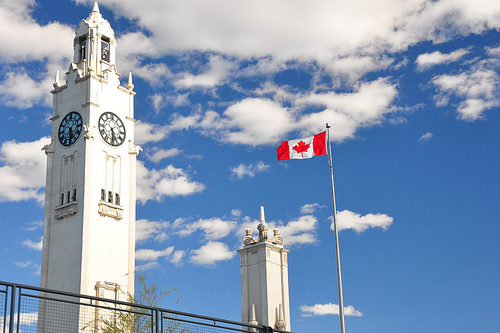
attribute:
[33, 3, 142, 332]
tower — white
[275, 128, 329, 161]
flag — red, canadian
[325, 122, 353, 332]
pole — silver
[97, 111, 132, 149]
clock — black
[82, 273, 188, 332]
tree — forefront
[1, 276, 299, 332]
fence — black, metal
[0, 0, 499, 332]
sky — sunny, blue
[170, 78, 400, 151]
clouds — white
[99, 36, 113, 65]
window — glass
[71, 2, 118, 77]
spire — white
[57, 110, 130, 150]
clocks — black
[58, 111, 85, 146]
clock — blue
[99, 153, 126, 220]
windows — arched